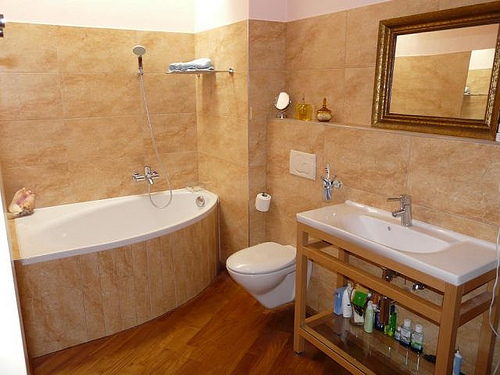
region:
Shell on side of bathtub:
[6, 186, 44, 213]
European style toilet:
[232, 220, 311, 304]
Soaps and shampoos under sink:
[339, 282, 426, 348]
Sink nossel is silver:
[386, 178, 421, 230]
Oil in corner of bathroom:
[286, 85, 338, 126]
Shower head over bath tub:
[126, 34, 182, 218]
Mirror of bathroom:
[388, 30, 490, 135]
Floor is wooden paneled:
[106, 312, 246, 365]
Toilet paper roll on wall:
[254, 180, 273, 212]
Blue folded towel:
[173, 48, 212, 77]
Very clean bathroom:
[71, 70, 499, 361]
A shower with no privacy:
[10, 25, 225, 335]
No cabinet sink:
[267, 155, 492, 371]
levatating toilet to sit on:
[190, 200, 390, 321]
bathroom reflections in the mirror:
[365, 15, 495, 155]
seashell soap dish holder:
[0, 162, 95, 232]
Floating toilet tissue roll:
[232, 140, 287, 220]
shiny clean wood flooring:
[45, 277, 321, 369]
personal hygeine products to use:
[326, 267, 461, 364]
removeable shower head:
[81, 33, 221, 206]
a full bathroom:
[1, 10, 498, 368]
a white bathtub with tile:
[10, 174, 235, 346]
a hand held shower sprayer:
[110, 36, 187, 221]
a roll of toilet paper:
[245, 181, 280, 225]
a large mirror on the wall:
[360, 9, 499, 171]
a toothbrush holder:
[301, 147, 344, 207]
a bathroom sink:
[294, 161, 499, 361]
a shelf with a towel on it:
[160, 40, 243, 87]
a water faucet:
[380, 185, 427, 242]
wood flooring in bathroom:
[55, 265, 375, 373]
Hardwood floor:
[27, 262, 352, 373]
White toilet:
[224, 240, 314, 308]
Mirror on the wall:
[370, 0, 499, 142]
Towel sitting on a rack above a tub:
[167, 55, 212, 73]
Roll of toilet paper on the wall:
[253, 191, 272, 211]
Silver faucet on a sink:
[386, 193, 415, 227]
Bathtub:
[3, 182, 218, 359]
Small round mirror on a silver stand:
[271, 90, 290, 117]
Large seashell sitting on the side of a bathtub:
[6, 185, 39, 220]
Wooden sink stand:
[293, 197, 499, 374]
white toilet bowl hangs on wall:
[218, 224, 326, 327]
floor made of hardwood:
[17, 280, 358, 373]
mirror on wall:
[351, 8, 498, 150]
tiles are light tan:
[0, 19, 221, 202]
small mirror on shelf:
[263, 82, 295, 127]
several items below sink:
[322, 271, 473, 371]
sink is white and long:
[300, 185, 497, 307]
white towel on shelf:
[161, 43, 240, 100]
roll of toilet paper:
[237, 174, 289, 235]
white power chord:
[487, 225, 498, 373]